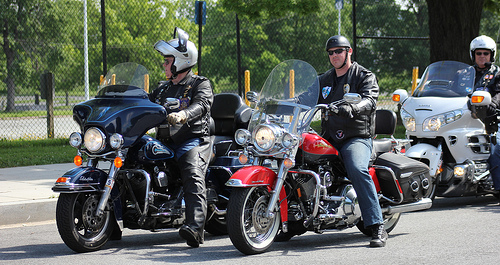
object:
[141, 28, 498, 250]
three motorcyclists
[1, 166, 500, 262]
road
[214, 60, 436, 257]
motorcycle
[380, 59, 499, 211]
motorcycle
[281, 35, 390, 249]
motorcyclist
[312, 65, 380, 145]
black outfit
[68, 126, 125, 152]
three lights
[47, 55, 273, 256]
motorcycle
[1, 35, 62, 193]
left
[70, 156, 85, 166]
orange lights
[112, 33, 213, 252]
motorcyclist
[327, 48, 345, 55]
sunglasses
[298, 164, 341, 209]
engine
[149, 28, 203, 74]
helmet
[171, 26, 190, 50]
visor up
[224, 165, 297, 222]
fender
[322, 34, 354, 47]
helmet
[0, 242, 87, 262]
shadow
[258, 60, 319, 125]
pillars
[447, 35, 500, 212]
motorcyclist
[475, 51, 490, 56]
sunglasses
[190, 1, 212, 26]
sign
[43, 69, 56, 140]
wooden post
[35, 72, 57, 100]
sign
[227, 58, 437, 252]
motorcycles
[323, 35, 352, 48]
helmets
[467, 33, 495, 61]
helmet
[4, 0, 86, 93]
trees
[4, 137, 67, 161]
grass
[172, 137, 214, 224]
leather chaps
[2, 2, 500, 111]
park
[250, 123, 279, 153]
front middle light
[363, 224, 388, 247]
shoes